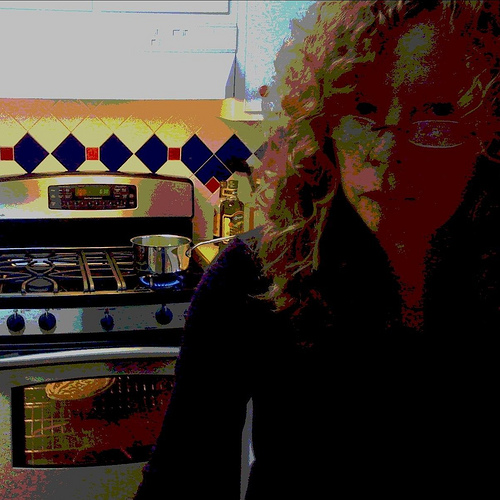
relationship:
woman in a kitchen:
[128, 0, 499, 498] [1, 1, 498, 498]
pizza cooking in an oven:
[41, 375, 117, 402] [0, 163, 232, 498]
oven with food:
[1, 172, 253, 499] [37, 378, 214, 450]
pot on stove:
[130, 232, 235, 274] [0, 170, 252, 498]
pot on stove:
[130, 232, 235, 274] [0, 170, 205, 498]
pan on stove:
[121, 216, 223, 301] [1, 205, 193, 330]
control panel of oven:
[1, 169, 196, 219] [0, 170, 205, 379]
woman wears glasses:
[128, 0, 499, 498] [322, 103, 484, 153]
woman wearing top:
[128, 0, 499, 498] [173, 222, 481, 479]